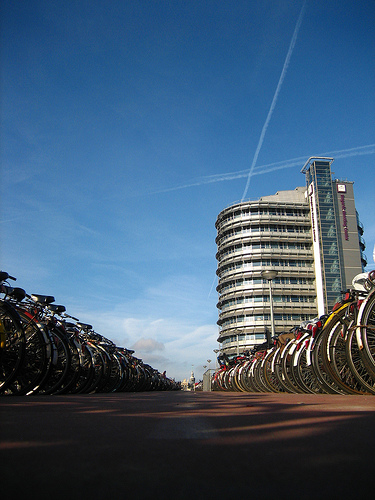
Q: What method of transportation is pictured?
A: Bike.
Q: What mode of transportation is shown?
A: Bicycles.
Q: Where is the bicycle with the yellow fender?
A: On the right side.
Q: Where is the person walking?
A: Between the rolls of bicycle.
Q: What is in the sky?
A: Clouds.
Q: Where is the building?
A: Behind the right roll of bicycles.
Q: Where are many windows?
A: Building.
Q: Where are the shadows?
A: On the pavement.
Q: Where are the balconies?
A: On the building.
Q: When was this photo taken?
A: Daytime.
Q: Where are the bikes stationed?
A: On bike racks.